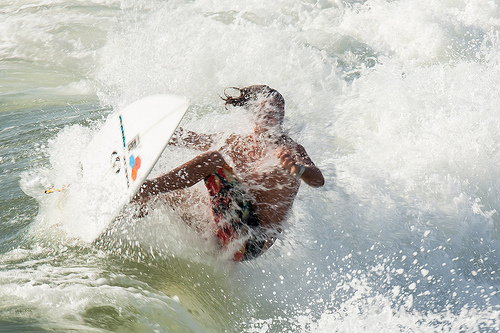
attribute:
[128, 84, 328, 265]
person — pictured, light skinned, bare chested, surfing, surfer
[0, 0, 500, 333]
ocean — splashing, rough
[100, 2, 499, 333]
wave — crashing, pictured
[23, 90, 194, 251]
surfboard — white, pictured, wooden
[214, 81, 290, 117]
hair — wet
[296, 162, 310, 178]
wristband — pictured, white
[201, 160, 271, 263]
shorts — black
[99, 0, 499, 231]
water — white